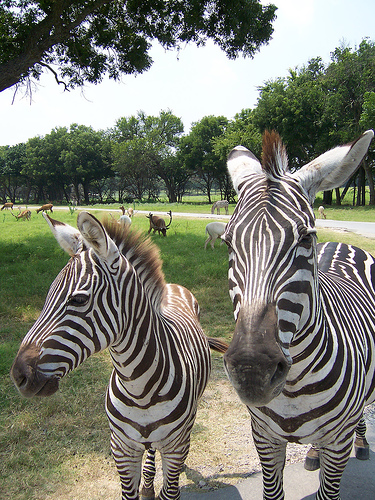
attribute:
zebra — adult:
[201, 114, 374, 495]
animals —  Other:
[1, 201, 327, 245]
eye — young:
[69, 291, 92, 304]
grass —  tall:
[170, 251, 223, 280]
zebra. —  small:
[160, 135, 373, 435]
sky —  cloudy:
[1, 2, 373, 161]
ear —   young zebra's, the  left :
[71, 207, 122, 267]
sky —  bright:
[287, 8, 337, 41]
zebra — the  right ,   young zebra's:
[14, 208, 210, 420]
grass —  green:
[147, 235, 229, 303]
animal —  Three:
[36, 203, 53, 213]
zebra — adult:
[210, 131, 369, 494]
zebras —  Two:
[5, 121, 373, 498]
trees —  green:
[4, 48, 372, 192]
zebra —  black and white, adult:
[222, 129, 374, 498]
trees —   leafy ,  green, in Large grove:
[1, 105, 225, 201]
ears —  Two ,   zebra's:
[41, 211, 112, 252]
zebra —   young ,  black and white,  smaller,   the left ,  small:
[13, 211, 214, 498]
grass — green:
[3, 207, 229, 497]